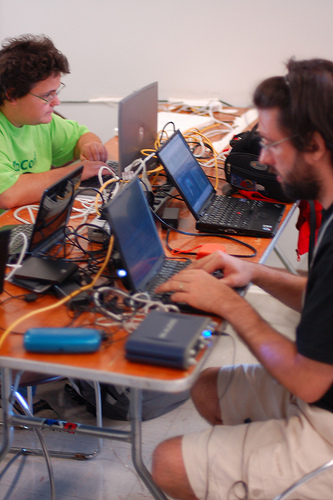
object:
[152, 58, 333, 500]
man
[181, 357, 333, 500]
shorts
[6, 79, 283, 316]
laptops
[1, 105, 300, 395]
table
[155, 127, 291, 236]
laptop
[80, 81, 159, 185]
laptop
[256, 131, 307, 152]
glasses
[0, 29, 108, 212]
man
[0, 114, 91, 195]
shirt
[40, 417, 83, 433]
sticker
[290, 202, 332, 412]
shirt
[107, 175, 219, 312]
laptop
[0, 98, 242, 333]
computer cables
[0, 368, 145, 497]
leg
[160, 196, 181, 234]
power adapter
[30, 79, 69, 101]
glasses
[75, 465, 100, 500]
floor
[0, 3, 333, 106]
wall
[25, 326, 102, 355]
case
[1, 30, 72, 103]
hair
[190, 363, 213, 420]
knee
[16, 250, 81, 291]
case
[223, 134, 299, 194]
modem